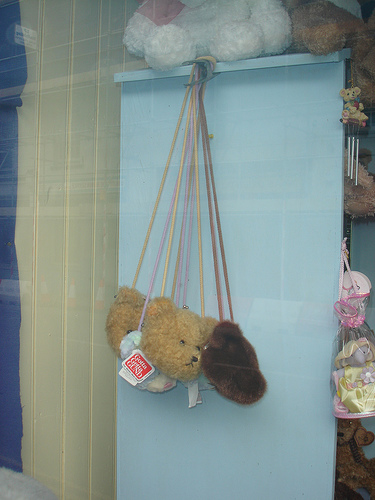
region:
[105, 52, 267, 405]
Stuffed animals purses hanging aside a tall shelf unit.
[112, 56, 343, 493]
Shelf unit is light blue colored.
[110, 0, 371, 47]
More stuffed animals on the top of the shelf unit.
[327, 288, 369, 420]
Stuffed animal in a plastic pouch.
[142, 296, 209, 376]
The purse is a furry bear's head.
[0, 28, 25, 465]
Curtain is blue.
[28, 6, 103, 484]
Wallpaper is light green with yellow stripes.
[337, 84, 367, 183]
Small bear seated on a stick.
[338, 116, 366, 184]
Stick has three chimes hanging on it.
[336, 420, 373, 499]
Brown bear seated at the bottom of the shelf unit.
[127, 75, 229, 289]
Rope holding the stuffed animals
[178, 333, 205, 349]
The eyes fo the stuffed animal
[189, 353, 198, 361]
The nose of the stuffed animal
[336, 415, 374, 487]
A stuffed animal near the ground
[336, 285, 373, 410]
A bag holding a stuffed animal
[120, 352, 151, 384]
A tag on the stuffed animal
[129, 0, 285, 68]
A large stuffed animal on the shelf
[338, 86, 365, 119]
A small stuffed bear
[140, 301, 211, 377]
A stuffed bear head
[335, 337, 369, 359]
The stuffed animal has a hat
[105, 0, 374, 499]
the stuffed animals on the shelf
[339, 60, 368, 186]
the windchime hanging from the shelf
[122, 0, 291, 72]
the white stuffed animal on the top of the shelf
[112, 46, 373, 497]
the light blue shelf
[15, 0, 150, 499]
the yellow wall paneling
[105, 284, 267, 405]
the heads of the stuffed animals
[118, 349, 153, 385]
the tags hanging from the stuffed animals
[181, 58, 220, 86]
the metal clip on the shelf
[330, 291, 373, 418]
the clear plastic bag hanging from the shelf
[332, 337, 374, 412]
the stuffed animal in the clear plastic bag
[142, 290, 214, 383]
the head of a bear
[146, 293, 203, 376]
the bear is tan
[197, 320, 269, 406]
a brown bear head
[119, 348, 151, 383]
a tag on the bear head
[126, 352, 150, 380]
the tag has words on it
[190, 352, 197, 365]
the nose of the bear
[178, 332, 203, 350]
the eyes of the teddy bear head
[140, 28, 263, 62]
legs of a teddy bear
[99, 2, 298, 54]
the teddy bear is white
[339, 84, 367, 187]
wind chimes hanging up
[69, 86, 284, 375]
teddy bear purses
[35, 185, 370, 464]
two teddy bear purses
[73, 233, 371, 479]
teddy bear purses for sale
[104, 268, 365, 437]
four teddy bear purses for sale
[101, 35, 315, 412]
teddy bear purses hanging on wall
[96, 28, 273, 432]
four teddy bear purses on a wall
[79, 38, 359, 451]
teddy bear purses hanging from shelf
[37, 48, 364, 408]
four teddy bear purses hanging from shelf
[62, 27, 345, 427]
purses hanging from shelf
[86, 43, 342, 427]
purses hanging from wall